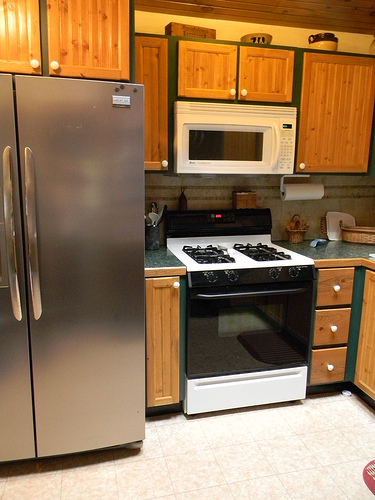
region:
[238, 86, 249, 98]
a white cabinet knob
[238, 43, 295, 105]
a brown cabinet door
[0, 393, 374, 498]
part of a tile floor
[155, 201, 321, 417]
a black and white oven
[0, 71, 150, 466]
part of a gray refrigerator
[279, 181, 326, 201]
a white paper towel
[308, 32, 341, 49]
a small bowl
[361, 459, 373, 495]
part of a red rug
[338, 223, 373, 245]
part of a brown basket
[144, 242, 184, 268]
a green counter top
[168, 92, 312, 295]
a white microwave on top a stove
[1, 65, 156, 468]
a big refrigerator in a kitchen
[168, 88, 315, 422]
a stove under a microwave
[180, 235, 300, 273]
burners of stove are black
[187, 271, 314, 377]
front door of an oven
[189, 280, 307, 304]
handle of oven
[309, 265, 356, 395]
drawers next to stove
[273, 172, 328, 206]
towel paper on a holder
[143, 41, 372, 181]
cabinets on side of microwave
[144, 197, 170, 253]
utensils in a cup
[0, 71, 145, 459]
Stainless steel refrigerator with four magnets.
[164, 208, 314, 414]
Black and white stove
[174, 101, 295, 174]
White microwave with a blue digital clock.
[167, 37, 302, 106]
Wooden cabinets with green paint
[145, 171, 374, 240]
Tiled backsplash behind paper towel holder.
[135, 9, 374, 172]
A box, pot, and bowl placed above the cabinets.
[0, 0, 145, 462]
Small wooden cabinets above the refrigerator.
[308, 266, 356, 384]
Small wooden drawers with white handles.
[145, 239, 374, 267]
Green countertops surrounding stove burners.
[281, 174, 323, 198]
Paper towels hanging from a paper towel holder.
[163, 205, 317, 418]
black and white gas stove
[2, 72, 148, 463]
stainless steel refigerator in the kitchen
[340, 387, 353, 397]
ant trap is on the floor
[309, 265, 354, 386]
three wooden drawers with white handles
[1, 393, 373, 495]
floor is light gray linoleum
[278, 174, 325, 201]
paper towels are under the cabinet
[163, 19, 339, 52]
decorations on top of cabinets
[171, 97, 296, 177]
white microwave is above the stove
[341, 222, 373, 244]
brown wicker basket sitting on the counter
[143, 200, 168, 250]
silver container on the counter is holding utensils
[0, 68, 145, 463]
Stainless steel fridge with french doors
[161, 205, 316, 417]
White and black range and oven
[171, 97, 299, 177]
Built in white microwave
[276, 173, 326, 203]
White paper towel dispenser with paper towels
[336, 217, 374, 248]
Empty wicker basket on the counter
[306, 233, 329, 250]
Blue spoon holder on the counter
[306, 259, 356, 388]
Three drawers with white knobs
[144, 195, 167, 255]
Container of utensils to the left of the stove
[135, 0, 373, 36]
Wooden slates on the ceiling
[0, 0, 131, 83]
Wooden cabinets above the fridge